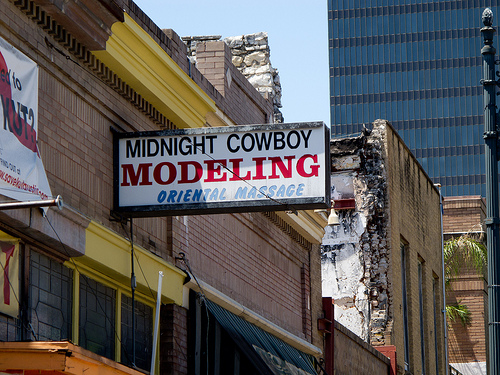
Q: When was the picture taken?
A: Daytime.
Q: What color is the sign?
A: White, black, red, and blue.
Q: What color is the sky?
A: Blue.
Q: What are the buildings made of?
A: Brick.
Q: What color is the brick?
A: Red.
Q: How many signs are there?
A: Two.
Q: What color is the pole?
A: Black.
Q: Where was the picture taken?
A: In the city.